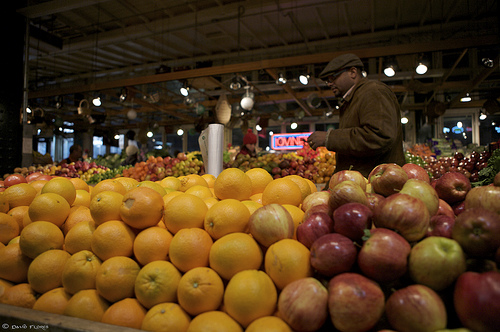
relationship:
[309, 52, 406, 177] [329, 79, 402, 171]
man wearing a jacket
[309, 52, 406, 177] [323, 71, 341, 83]
man wearing glasses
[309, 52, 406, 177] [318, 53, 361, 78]
man wearing hat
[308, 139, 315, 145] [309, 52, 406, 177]
ring on man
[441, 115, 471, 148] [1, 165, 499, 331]
window near fruits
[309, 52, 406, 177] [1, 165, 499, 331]
man near fruits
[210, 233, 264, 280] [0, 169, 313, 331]
orange in stack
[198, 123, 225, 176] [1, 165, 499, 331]
plastic bags near fruits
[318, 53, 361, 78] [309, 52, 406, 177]
hat on man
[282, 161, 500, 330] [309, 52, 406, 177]
apples are in front of man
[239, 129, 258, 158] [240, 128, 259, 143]
woman wears a beanie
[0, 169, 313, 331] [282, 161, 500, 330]
oranges next to apples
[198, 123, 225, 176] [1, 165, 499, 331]
plastic bags for fruits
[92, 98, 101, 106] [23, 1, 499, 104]
light on ceiling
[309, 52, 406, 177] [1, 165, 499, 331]
man shopping fruits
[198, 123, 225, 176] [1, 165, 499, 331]
plastic bags used for fruits